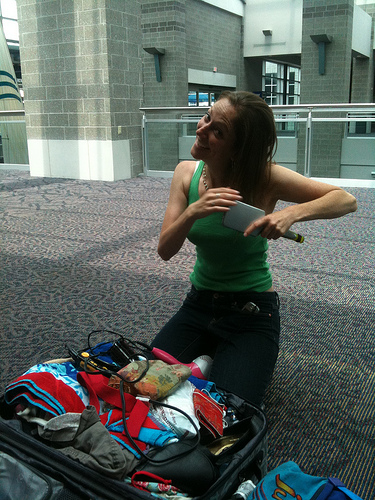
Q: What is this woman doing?
A: Brushing hair.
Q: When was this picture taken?
A: Daytime.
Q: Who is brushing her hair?
A: A woman.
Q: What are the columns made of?
A: Brick.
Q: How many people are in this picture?
A: One.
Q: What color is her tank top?
A: Green.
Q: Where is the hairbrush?
A: Left hand.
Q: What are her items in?
A: Luggage.